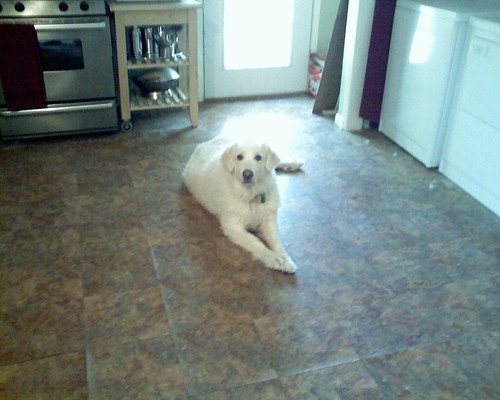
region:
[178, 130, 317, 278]
white dog laying on the floor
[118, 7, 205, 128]
some kitchenware sitting on the shelves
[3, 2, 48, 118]
black towel hanging from oven handle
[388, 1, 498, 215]
the washer and dryer are in the kitchen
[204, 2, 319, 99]
door going into and out of the kitchen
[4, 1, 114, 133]
an oven with black knobs sits in the kitchen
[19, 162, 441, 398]
marble style flooring covers the kitchen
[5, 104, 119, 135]
bottom drawer of the oven for storage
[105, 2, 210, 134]
a kitchen cart holds kitchenwares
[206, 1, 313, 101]
the back door is closed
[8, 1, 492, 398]
dog waiting hopefully in kitchen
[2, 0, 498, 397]
large dog lying on kitchen floor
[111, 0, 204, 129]
butcher block kitchen table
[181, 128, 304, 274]
yellow labrador retriever mix dog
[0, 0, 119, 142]
stainless steel stove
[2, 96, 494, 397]
linoleum tile floor with curling tile edges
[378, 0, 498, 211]
matching white washer and dryer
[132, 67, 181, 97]
dark metal cooking wok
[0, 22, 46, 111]
maroon towel hanging on oven door handle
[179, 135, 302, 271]
reclining yellow labrador mix dog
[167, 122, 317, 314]
a white dog laying on the floor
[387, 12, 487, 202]
a white washer and dryer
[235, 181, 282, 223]
a dog wearing a collar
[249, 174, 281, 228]
a dog wearing a green tag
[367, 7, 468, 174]
a white washing machine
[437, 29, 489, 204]
a white clothes dryer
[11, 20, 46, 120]
a towel hanging on the handle of a oven door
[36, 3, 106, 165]
a silver oven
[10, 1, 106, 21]
black control knobs for a oven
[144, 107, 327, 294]
a solid white dog on the floor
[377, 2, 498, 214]
front of two white appliances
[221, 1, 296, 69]
natural light through windows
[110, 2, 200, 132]
wood cart with wheel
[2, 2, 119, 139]
front of silver oven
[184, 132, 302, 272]
dog laying on floor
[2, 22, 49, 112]
towel on metal rack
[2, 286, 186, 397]
buckling tiles on floor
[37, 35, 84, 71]
window on front of oven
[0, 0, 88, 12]
black knobs on appliance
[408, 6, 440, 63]
light reflection on appliance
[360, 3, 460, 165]
a white clothes washer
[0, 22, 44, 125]
a brown towel hanging on the handle of a oven door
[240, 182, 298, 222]
a white dog wearing a green tag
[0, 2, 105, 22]
black control knobs on a oven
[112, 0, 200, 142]
a wood table with wheels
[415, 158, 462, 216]
a piece of paper on the floor